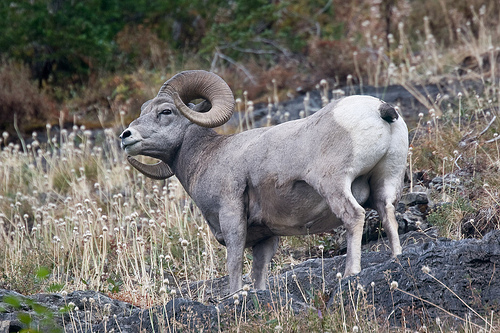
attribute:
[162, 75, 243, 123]
horn — large, curvier, big, curled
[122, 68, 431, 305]
ram — looking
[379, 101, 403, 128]
tail — small, short, stubby, black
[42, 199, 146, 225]
buds — small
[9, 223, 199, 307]
plants — dried, wild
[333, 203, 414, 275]
legs — white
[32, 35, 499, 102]
grass — dried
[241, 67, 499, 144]
terrain — rocky, rough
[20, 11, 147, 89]
bush — green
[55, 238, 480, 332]
weed — green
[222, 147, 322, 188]
coat — grey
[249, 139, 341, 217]
body — grey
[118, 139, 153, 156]
muzzle — white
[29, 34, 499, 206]
hillside — green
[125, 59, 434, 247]
sheep — bighorn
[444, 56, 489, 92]
rock — gray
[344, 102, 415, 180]
rump — white